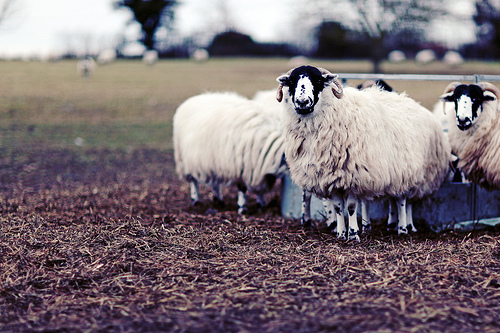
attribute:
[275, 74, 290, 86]
ear —  right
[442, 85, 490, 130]
face — black, white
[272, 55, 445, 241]
sheep — white, black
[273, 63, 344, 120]
face — black, white, Black and white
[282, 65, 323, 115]
face — black, white, Black and white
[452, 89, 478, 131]
face — black, white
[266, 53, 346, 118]
face — white,  black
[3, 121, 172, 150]
grass — blurred, green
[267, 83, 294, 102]
horn — brown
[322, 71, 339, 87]
left ear —  left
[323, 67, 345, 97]
horn — curled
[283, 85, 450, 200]
wool — large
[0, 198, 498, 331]
twig — small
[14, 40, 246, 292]
yard — green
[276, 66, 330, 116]
face — sheep's, black , white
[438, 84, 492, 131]
face —  black, white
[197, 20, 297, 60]
building — large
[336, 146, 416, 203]
wool — long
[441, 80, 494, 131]
face — black, white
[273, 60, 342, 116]
face — black, white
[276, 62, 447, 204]
sheep — Black and white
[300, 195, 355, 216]
spots — black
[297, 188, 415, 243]
legs — white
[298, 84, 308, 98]
spots — black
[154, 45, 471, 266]
sheep — blurred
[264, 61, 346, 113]
face — black, white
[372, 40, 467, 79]
bundles — white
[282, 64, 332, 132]
face — Black and white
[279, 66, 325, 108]
face — Black and white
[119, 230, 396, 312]
ground — dirt